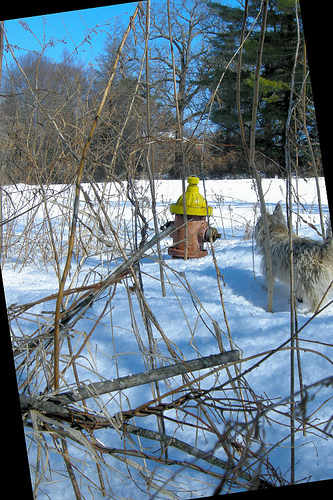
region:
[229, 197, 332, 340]
small dog in the snow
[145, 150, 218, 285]
fire hydrant in the snow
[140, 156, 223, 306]
red and yellow fire hydrant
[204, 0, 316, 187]
pine tree with green needles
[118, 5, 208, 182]
tall, leafless tree in winter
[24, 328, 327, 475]
dead branches in winter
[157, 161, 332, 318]
white dog investigating fire hydrant in winter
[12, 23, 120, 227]
sunny winter day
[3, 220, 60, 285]
tall dead grass in the snow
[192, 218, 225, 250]
water outlet for connecting fire hose to the hydrant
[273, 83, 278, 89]
leaves of a tree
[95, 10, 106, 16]
section of blue sky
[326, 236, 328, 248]
tail of a dog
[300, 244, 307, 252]
part of dog's body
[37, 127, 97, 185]
section of wooden plantation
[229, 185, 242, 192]
section of white snow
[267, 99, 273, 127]
section of a stem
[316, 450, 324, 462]
part of a snowy surface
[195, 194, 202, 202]
yellow part of a water outlet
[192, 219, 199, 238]
section of a water outlet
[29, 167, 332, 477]
snow is on the ground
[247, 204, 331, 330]
a dog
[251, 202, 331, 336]
a dog is standing in the snow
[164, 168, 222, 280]
a fire hydrant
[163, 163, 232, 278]
a fire hydrant is in the snow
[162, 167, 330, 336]
the dog walks towards the fire hydrant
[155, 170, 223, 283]
the hydrant is orange and yellow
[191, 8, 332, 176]
pine trees by the field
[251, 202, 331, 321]
the dog is white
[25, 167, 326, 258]
the fire hydrant is at the edge of a field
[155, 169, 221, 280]
a yellow and red fire hydrant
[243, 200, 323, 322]
a scruffy haired dog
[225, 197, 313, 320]
a small dog looking across field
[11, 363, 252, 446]
several tree limbs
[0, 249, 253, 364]
white show on the ground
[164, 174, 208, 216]
yellow top of a fire hydrant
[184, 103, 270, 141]
green trees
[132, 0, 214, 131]
a tall tree with no leaves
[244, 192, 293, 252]
a small dogs ear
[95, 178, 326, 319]
a small dog looking at a fire hydrant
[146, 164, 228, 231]
Fire hydrant with a yellow top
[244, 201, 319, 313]
A white dog in the snow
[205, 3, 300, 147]
Tall green pines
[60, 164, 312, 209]
A snowy field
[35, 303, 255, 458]
Bare twigs bunched together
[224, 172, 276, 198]
Light shining on the snow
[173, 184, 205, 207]
Fading yellow paint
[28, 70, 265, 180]
Trees border a field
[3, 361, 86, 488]
The side of a window frame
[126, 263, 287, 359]
A bluish glow in the snow